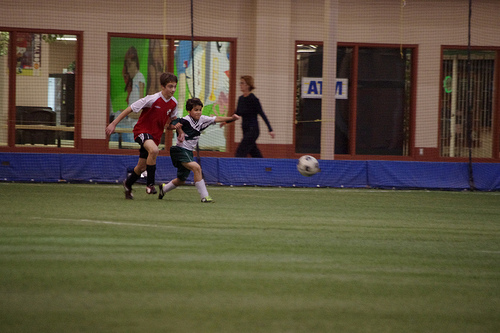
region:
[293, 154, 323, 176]
a black and white soccer ball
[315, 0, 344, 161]
a large white pole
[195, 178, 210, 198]
a boy's white sock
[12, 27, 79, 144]
a large window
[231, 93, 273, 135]
a woman's black shirt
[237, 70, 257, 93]
a woman's short cut hair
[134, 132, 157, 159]
a boy's black and white shorts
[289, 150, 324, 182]
Soccer ball in motion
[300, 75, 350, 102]
ATM information sign on windows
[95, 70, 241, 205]
Boys playing indoor soccer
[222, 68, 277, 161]
Woman walking around soccer field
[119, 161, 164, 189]
Black soccer socks on boy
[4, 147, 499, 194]
Blue wall boundary of soccer field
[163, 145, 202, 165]
Green shorts on boy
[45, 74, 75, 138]
Vending machine in break room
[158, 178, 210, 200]
White socks on boy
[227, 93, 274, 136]
Black shirt on woman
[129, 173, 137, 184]
boy wearing black socks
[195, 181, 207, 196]
boy wearing white socks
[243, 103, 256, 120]
woman wearing black shirt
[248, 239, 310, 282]
green grass in field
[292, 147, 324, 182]
volley ball in mid air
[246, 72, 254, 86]
woman with blonde hair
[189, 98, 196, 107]
boy with black hair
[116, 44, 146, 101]
woman in painting on wall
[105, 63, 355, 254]
children playing soccer on field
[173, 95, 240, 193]
child wearing a soccer uniform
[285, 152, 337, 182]
soccer ball in the air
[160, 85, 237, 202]
boy wearing a soccer uniform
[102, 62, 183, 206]
boy wearing a soccer uniform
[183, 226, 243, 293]
green soccer field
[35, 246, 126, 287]
green soccer field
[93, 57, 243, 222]
Two boys play soccer in a field.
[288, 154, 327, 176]
A soccer ball flies across the field.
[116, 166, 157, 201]
This boy is wearing black socks.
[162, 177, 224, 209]
This boy is wearing white socks.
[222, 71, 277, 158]
A woman walks by the game.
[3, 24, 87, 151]
A large doorway leads into a room with a vending machine.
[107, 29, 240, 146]
A large mural on the wall.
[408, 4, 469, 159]
A large black net covers the field.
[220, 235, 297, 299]
the green soccer field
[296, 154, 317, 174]
a soccer ball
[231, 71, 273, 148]
a women walking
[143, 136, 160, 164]
a boys leg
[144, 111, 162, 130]
a red shirt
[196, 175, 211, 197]
a white sock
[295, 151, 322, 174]
white and black soccer ball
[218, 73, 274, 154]
woman wearing all black clothing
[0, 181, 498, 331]
green grass soccer field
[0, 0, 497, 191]
black nylon safety net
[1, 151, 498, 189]
blue barrier padding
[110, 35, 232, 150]
multi colored wall mural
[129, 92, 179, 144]
red and white soccer jersey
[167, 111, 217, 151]
white and green soccer jersey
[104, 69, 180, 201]
tall soccer player with light brown hair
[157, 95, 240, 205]
short soccer player with dark brown hair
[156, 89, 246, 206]
boy running after ball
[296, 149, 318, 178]
soccer ball in air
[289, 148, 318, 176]
ball in air is soccer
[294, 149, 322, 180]
bal in air is black and white